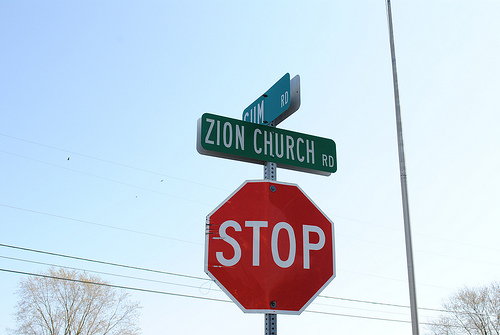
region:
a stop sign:
[202, 178, 337, 316]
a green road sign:
[195, 113, 338, 175]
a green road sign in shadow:
[240, 70, 302, 127]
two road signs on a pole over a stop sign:
[195, 71, 339, 333]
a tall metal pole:
[385, 0, 418, 334]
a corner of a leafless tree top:
[435, 283, 499, 333]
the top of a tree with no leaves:
[9, 264, 140, 334]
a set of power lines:
[0, 241, 499, 330]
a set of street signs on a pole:
[195, 72, 338, 334]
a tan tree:
[9, 263, 146, 334]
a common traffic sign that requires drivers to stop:
[201, 179, 334, 312]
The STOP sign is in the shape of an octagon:
[206, 179, 337, 311]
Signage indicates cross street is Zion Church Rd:
[202, 112, 339, 173]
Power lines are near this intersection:
[1, 238, 180, 295]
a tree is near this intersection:
[14, 260, 138, 333]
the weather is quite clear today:
[17, 16, 164, 222]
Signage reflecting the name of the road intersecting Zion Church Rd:
[234, 83, 296, 126]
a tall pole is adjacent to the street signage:
[381, 20, 434, 302]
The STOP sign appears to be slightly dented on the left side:
[204, 179, 334, 309]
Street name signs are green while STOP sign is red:
[199, 73, 336, 312]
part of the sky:
[145, 97, 190, 157]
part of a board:
[239, 263, 250, 273]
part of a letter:
[278, 218, 303, 232]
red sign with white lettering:
[199, 180, 341, 320]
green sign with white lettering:
[189, 83, 336, 173]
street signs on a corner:
[185, 84, 355, 191]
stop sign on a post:
[198, 183, 350, 320]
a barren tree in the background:
[14, 250, 134, 333]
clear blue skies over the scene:
[65, 28, 170, 212]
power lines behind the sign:
[18, 238, 219, 323]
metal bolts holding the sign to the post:
[264, 169, 286, 316]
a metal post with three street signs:
[187, 81, 331, 333]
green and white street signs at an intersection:
[200, 100, 340, 167]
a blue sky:
[5, 8, 499, 245]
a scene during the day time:
[7, 6, 498, 333]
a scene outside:
[3, 11, 487, 333]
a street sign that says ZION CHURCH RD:
[189, 103, 350, 180]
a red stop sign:
[182, 171, 346, 315]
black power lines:
[5, 229, 496, 333]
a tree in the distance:
[5, 255, 146, 333]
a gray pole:
[383, 0, 437, 334]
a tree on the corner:
[419, 271, 499, 333]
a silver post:
[247, 146, 289, 333]